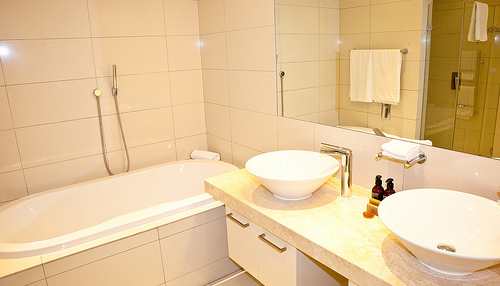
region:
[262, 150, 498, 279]
two sinks on the counter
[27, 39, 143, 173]
shower hose on the walll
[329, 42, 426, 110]
towels on bar reflection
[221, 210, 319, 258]
two handles on drawer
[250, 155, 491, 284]
sinks are above the counter top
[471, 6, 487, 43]
towel hanging from glass door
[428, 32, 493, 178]
glass doors on the shower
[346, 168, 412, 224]
toiletries on the counter top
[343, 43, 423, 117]
towels are white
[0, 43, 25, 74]
light reflection on the wall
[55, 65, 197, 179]
the room is clean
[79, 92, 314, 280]
the room is clean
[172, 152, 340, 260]
the room is clean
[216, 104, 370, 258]
the room is clean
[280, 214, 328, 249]
the room is clean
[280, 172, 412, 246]
the room is clean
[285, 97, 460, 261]
the room is clean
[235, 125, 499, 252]
Sinks in bathroom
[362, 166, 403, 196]
Small brown shampoos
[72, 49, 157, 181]
Shower head of bathtub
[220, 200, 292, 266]
Handles on cabinet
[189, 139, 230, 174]
Small towel in corner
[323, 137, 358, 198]
Head of sink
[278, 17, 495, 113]
Bathroom mirror is reflective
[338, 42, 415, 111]
Towel hanging on rack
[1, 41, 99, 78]
White tile on wall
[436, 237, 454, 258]
Drain of sink is metal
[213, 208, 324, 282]
a drawer under a sink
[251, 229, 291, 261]
a steel drawer handle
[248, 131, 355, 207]
an above counter sink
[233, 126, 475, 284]
a double sink counter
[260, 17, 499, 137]
a large mirror with no frame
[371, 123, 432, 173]
washclothes on a holder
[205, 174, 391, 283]
a marble bathroom counter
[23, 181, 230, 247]
an empty tub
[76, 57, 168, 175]
a shower hose attached to the wall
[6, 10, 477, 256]
a pristine clean bathroom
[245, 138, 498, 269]
two white ceramic sinks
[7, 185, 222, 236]
large white bath tub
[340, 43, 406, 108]
white towel hanging on rack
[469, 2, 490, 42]
white towel hanging from shower door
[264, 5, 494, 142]
reflection of shower in mirror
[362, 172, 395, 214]
hand soaps on sink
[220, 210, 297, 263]
two metal silver handles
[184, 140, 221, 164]
white towel on bath tub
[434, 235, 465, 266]
silver drain in sink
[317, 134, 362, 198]
metal silver faucet